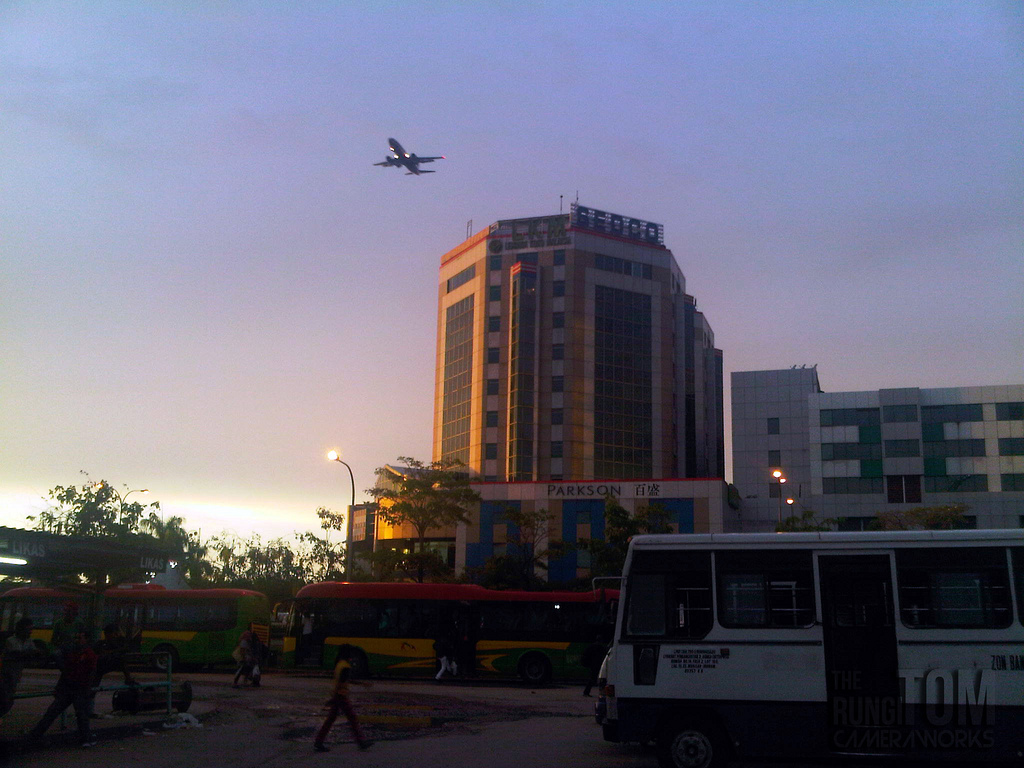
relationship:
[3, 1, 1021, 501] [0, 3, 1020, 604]
clouds in sky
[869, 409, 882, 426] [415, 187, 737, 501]
window on building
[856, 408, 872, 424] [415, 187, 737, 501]
window on building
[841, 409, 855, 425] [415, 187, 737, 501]
window on building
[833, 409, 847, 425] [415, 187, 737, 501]
window on building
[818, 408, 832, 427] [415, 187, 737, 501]
window on building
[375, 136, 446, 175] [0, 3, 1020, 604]
jet in sky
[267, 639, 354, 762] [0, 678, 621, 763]
people in street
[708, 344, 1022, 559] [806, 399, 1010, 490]
building has windows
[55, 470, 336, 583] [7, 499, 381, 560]
trees on background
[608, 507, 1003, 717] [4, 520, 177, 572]
train with logo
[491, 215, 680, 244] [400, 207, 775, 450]
letters are in building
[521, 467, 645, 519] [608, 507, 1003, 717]
writing on side of train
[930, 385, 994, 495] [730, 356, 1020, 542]
windows are on building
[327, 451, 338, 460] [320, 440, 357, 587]
light on pole